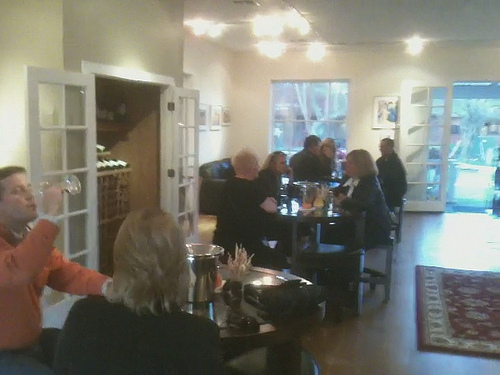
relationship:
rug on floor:
[412, 259, 499, 364] [290, 212, 498, 375]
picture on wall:
[370, 94, 402, 129] [227, 45, 499, 159]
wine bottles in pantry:
[98, 144, 132, 174] [95, 76, 164, 274]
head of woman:
[110, 208, 188, 307] [46, 205, 221, 374]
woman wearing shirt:
[329, 147, 392, 242] [337, 177, 360, 197]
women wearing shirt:
[212, 148, 278, 256] [213, 177, 265, 251]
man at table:
[1, 161, 111, 374] [188, 248, 322, 374]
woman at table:
[46, 205, 221, 374] [188, 248, 322, 374]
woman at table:
[329, 147, 392, 242] [275, 197, 342, 275]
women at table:
[212, 148, 278, 256] [275, 197, 342, 275]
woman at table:
[263, 148, 295, 196] [275, 197, 342, 275]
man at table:
[372, 137, 410, 203] [325, 169, 351, 183]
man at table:
[291, 133, 330, 180] [325, 169, 351, 183]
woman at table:
[321, 130, 338, 174] [325, 169, 351, 183]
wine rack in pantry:
[97, 138, 131, 274] [95, 76, 164, 274]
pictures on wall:
[195, 102, 235, 134] [182, 29, 227, 163]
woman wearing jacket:
[329, 147, 392, 242] [340, 178, 395, 241]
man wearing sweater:
[1, 161, 111, 374] [3, 219, 109, 349]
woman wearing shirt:
[46, 205, 221, 374] [53, 315, 219, 374]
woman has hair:
[46, 205, 221, 374] [101, 204, 191, 314]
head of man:
[0, 164, 41, 231] [1, 161, 111, 374]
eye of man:
[10, 182, 25, 199] [1, 161, 111, 374]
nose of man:
[22, 189, 38, 203] [1, 161, 111, 374]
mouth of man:
[24, 198, 43, 212] [1, 161, 111, 374]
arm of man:
[0, 215, 64, 295] [1, 161, 111, 374]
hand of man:
[41, 178, 65, 221] [1, 161, 111, 374]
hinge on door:
[164, 97, 174, 114] [171, 89, 199, 242]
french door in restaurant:
[22, 64, 99, 329] [1, 1, 499, 374]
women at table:
[212, 145, 399, 256] [275, 197, 342, 275]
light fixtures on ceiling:
[192, 10, 324, 58] [185, 2, 498, 46]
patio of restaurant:
[429, 153, 499, 199] [1, 1, 499, 374]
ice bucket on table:
[180, 237, 224, 304] [188, 248, 322, 374]